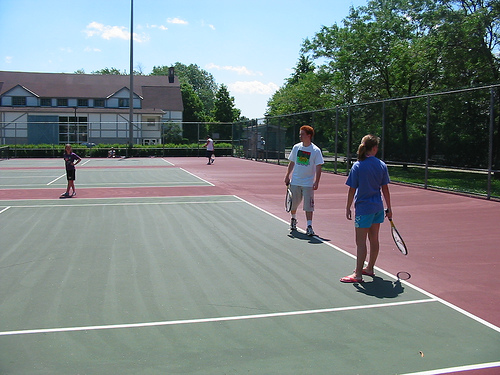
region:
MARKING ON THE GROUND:
[230, 310, 250, 326]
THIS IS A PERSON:
[290, 115, 322, 245]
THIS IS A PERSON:
[345, 113, 393, 281]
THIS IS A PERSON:
[61, 135, 76, 191]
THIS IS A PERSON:
[201, 130, 217, 167]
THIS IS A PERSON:
[106, 139, 123, 162]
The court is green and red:
[187, 165, 222, 190]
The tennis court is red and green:
[184, 172, 219, 194]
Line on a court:
[201, 307, 261, 329]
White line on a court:
[219, 303, 272, 333]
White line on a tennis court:
[228, 310, 274, 330]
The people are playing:
[259, 117, 418, 292]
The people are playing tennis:
[266, 121, 422, 298]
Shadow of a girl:
[358, 265, 416, 314]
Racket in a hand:
[382, 200, 417, 262]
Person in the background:
[198, 134, 218, 168]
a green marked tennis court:
[1, 197, 498, 374]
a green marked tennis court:
[2, 167, 215, 188]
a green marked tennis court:
[0, 156, 173, 166]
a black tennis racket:
[282, 185, 289, 212]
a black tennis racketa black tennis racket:
[390, 222, 407, 257]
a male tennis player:
[281, 124, 324, 239]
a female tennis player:
[341, 133, 406, 283]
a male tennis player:
[201, 134, 216, 165]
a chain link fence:
[232, 82, 499, 203]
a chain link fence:
[0, 119, 235, 154]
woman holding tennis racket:
[338, 128, 413, 289]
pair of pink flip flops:
[336, 258, 376, 285]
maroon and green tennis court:
[2, 150, 497, 372]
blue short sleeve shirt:
[343, 153, 395, 218]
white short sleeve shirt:
[281, 139, 326, 193]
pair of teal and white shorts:
[347, 205, 387, 232]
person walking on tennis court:
[56, 140, 85, 205]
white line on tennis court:
[1, 287, 448, 347]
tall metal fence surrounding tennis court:
[0, 78, 499, 206]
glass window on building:
[14, 97, 26, 104]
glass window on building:
[56, 95, 68, 108]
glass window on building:
[76, 98, 89, 107]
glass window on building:
[93, 100, 103, 108]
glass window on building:
[119, 97, 128, 106]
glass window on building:
[59, 116, 69, 126]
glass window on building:
[58, 124, 68, 134]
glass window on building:
[56, 133, 71, 142]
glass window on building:
[77, 126, 87, 135]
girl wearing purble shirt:
[335, 132, 427, 292]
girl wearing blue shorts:
[328, 128, 413, 298]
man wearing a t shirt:
[280, 111, 327, 247]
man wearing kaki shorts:
[266, 116, 336, 251]